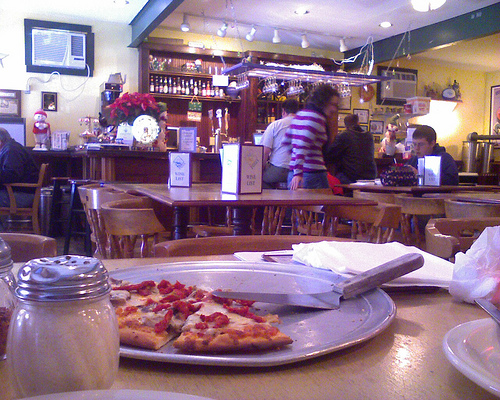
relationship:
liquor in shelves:
[150, 74, 227, 96] [141, 40, 348, 174]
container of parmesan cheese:
[7, 247, 127, 394] [3, 303, 129, 396]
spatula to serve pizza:
[203, 243, 434, 312] [105, 255, 397, 368]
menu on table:
[215, 138, 268, 198] [132, 179, 379, 231]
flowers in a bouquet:
[105, 89, 169, 152] [102, 85, 164, 121]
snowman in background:
[28, 106, 54, 153] [0, 12, 272, 142]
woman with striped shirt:
[284, 79, 341, 194] [280, 108, 328, 176]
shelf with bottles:
[145, 72, 233, 132] [150, 74, 227, 96]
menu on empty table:
[215, 138, 268, 198] [132, 179, 379, 231]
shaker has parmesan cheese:
[7, 247, 127, 394] [3, 303, 129, 396]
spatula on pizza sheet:
[203, 243, 434, 312] [105, 255, 397, 368]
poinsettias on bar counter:
[102, 85, 164, 121] [80, 126, 216, 160]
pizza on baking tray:
[110, 266, 290, 364] [105, 255, 397, 368]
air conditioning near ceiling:
[25, 20, 94, 75] [8, 1, 490, 19]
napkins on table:
[290, 233, 464, 289] [15, 242, 499, 398]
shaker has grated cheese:
[7, 247, 127, 394] [3, 303, 129, 396]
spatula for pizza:
[203, 243, 434, 312] [110, 266, 290, 364]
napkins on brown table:
[290, 233, 464, 289] [15, 242, 499, 398]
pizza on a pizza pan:
[110, 266, 290, 364] [105, 255, 397, 368]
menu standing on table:
[215, 138, 268, 198] [132, 179, 379, 231]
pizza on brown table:
[110, 266, 290, 364] [15, 242, 499, 398]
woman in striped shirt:
[284, 79, 341, 194] [280, 108, 328, 176]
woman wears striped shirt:
[284, 79, 341, 194] [280, 108, 328, 176]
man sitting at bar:
[330, 112, 385, 186] [68, 122, 464, 175]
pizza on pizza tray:
[110, 266, 290, 364] [105, 255, 397, 368]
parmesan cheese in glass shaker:
[3, 303, 129, 396] [7, 247, 127, 394]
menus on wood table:
[164, 138, 271, 199] [132, 179, 379, 231]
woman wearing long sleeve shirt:
[284, 79, 341, 194] [280, 108, 328, 176]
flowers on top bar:
[105, 89, 169, 152] [68, 122, 464, 175]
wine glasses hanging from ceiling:
[261, 77, 358, 98] [8, 1, 490, 19]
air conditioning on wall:
[25, 20, 94, 75] [5, 7, 133, 108]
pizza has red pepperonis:
[110, 266, 290, 364] [138, 274, 249, 328]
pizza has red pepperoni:
[110, 266, 290, 364] [214, 315, 234, 328]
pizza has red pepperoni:
[110, 266, 290, 364] [223, 301, 254, 314]